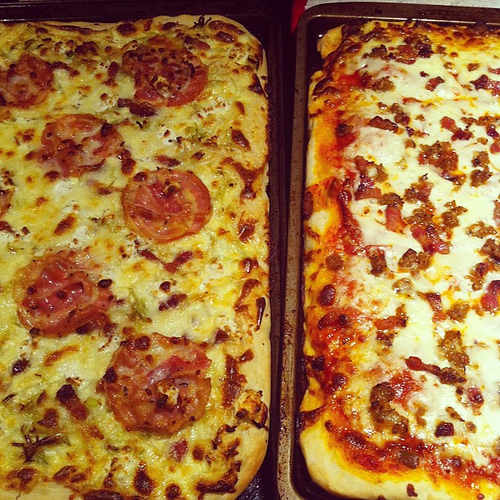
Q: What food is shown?
A: Pizza.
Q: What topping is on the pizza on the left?
A: Pepperoni.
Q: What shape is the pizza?
A: Rectangular.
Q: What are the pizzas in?
A: Pans.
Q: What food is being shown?
A: Pizza.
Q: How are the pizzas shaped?
A: Like squares.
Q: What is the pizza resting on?
A: Pans.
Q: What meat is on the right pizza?
A: Sausage.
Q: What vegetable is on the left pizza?
A: Tomato.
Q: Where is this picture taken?
A: A kitchen.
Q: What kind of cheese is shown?
A: White.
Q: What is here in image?
A: Pizza.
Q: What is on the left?
A: Pepperoni pizza.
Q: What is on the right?
A: Sausage pizza.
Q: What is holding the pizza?
A: Tin pan.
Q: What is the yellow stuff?
A: Cheese.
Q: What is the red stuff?
A: Sauce.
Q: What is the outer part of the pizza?
A: Crust.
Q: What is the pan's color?
A: Silver.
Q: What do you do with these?
A: Eat them.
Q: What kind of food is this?
A: Pizza.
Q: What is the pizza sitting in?
A: Pizza pan.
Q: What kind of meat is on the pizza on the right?
A: Sausage.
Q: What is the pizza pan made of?
A: Metal.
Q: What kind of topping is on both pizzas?
A: Cheese.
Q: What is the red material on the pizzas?
A: Sauce.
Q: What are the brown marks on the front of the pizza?
A: Burn marks.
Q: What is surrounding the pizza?
A: Pizza crust.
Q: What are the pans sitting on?
A: Hard surface.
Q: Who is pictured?
A: No one.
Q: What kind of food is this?
A: Pizza.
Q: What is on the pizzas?
A: Cheese.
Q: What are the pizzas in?
A: Pans.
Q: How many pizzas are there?
A: Two.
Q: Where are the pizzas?
A: In the pan.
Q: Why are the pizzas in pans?
A: Because they were cooked in the oven.